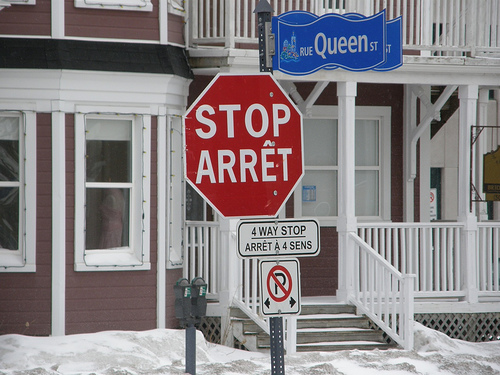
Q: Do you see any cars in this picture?
A: No, there are no cars.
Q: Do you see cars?
A: No, there are no cars.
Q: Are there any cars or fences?
A: No, there are no cars or fences.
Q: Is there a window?
A: Yes, there is a window.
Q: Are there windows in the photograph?
A: Yes, there is a window.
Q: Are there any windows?
A: Yes, there is a window.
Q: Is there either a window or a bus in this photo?
A: Yes, there is a window.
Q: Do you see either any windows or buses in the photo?
A: Yes, there is a window.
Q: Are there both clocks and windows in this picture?
A: No, there is a window but no clocks.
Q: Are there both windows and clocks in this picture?
A: No, there is a window but no clocks.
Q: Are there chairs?
A: No, there are no chairs.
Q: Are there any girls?
A: No, there are no girls.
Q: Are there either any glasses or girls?
A: No, there are no girls or glasses.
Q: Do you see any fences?
A: No, there are no fences.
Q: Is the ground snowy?
A: Yes, the ground is snowy.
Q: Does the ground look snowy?
A: Yes, the ground is snowy.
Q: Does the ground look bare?
A: No, the ground is snowy.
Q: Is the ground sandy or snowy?
A: The ground is snowy.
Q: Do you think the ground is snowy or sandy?
A: The ground is snowy.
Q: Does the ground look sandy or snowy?
A: The ground is snowy.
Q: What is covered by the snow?
A: The ground is covered by the snow.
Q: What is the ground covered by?
A: The ground is covered by the snow.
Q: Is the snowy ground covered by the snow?
A: Yes, the ground is covered by the snow.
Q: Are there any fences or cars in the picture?
A: No, there are no cars or fences.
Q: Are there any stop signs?
A: Yes, there is a stop sign.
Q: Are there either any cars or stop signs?
A: Yes, there is a stop sign.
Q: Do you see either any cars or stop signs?
A: Yes, there is a stop sign.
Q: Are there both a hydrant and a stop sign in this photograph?
A: No, there is a stop sign but no fire hydrants.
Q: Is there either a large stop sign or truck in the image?
A: Yes, there is a large stop sign.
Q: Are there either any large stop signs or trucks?
A: Yes, there is a large stop sign.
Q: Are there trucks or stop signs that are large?
A: Yes, the stop sign is large.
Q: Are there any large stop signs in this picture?
A: Yes, there is a large stop sign.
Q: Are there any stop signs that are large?
A: Yes, there is a stop sign that is large.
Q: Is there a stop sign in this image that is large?
A: Yes, there is a stop sign that is large.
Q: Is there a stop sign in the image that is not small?
A: Yes, there is a large stop sign.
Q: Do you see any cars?
A: No, there are no cars.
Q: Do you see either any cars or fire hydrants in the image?
A: No, there are no cars or fire hydrants.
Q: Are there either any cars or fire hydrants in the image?
A: No, there are no cars or fire hydrants.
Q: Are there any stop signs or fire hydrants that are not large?
A: No, there is a stop sign but it is large.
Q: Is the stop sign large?
A: Yes, the stop sign is large.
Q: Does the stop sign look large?
A: Yes, the stop sign is large.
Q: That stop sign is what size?
A: The stop sign is large.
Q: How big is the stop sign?
A: The stop sign is large.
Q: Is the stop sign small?
A: No, the stop sign is large.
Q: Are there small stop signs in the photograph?
A: No, there is a stop sign but it is large.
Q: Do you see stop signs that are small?
A: No, there is a stop sign but it is large.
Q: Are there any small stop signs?
A: No, there is a stop sign but it is large.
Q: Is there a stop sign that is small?
A: No, there is a stop sign but it is large.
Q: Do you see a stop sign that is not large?
A: No, there is a stop sign but it is large.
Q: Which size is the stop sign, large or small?
A: The stop sign is large.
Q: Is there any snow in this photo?
A: Yes, there is snow.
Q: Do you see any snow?
A: Yes, there is snow.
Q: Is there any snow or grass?
A: Yes, there is snow.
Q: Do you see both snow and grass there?
A: No, there is snow but no grass.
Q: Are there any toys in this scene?
A: No, there are no toys.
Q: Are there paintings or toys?
A: No, there are no toys or paintings.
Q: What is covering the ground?
A: The snow is covering the ground.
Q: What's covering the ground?
A: The snow is covering the ground.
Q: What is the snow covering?
A: The snow is covering the ground.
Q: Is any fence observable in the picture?
A: No, there are no fences.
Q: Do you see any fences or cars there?
A: No, there are no fences or cars.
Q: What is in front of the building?
A: The steps are in front of the building.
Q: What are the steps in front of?
A: The steps are in front of the building.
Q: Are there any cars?
A: No, there are no cars.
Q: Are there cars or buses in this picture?
A: No, there are no cars or buses.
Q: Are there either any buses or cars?
A: No, there are no cars or buses.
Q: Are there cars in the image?
A: No, there are no cars.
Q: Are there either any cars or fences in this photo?
A: No, there are no cars or fences.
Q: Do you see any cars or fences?
A: No, there are no cars or fences.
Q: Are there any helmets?
A: No, there are no helmets.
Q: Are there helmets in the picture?
A: No, there are no helmets.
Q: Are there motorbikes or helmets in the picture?
A: No, there are no helmets or motorbikes.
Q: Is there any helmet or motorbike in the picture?
A: No, there are no helmets or motorcycles.